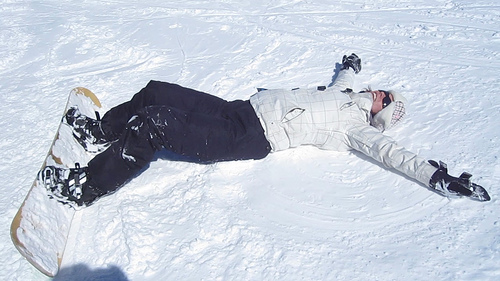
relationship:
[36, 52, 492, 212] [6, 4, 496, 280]
lady laying in snow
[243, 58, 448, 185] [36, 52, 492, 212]
coat on lady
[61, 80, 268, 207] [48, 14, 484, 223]
pants on snowboarder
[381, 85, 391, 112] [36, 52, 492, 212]
sunglasses on face of lady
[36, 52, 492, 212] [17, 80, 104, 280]
lady using snowboard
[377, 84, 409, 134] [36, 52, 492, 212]
hat on head of lady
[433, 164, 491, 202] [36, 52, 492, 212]
glove on left hand of lady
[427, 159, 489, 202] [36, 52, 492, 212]
glove on right hand of lady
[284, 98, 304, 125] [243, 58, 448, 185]
pocket on coat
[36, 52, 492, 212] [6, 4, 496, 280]
lady on snow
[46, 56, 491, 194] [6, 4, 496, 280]
lady on snow